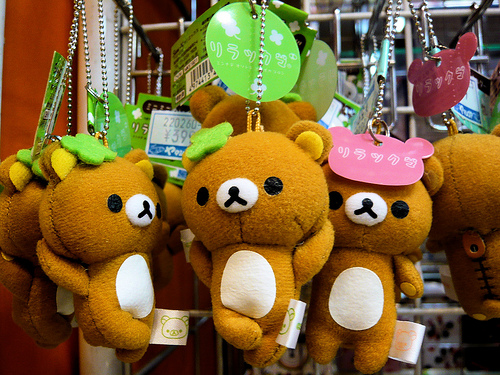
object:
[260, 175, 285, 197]
eye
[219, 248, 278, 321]
tummy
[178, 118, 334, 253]
head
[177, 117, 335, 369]
bear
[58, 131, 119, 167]
bow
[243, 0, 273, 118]
chain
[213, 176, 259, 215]
snout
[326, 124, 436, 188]
tag